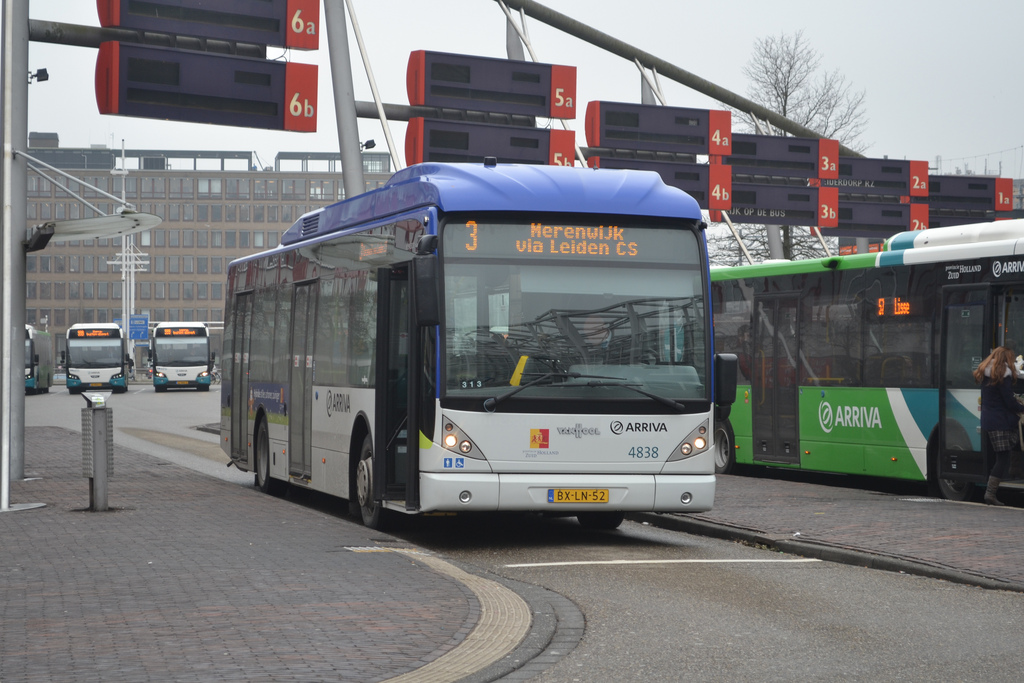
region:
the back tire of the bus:
[243, 407, 279, 488]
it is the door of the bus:
[366, 269, 439, 491]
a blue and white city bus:
[205, 149, 728, 535]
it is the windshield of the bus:
[439, 258, 703, 398]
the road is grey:
[176, 404, 982, 680]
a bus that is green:
[694, 243, 1023, 507]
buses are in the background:
[54, 315, 220, 411]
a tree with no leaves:
[742, 28, 841, 248]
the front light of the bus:
[661, 423, 719, 472]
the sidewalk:
[160, 588, 279, 633]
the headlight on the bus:
[678, 430, 701, 444]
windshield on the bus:
[443, 244, 691, 412]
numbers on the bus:
[620, 433, 656, 462]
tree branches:
[764, 45, 832, 109]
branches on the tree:
[746, 36, 819, 112]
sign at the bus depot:
[90, 0, 318, 49]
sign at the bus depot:
[89, 40, 315, 132]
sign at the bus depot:
[402, 46, 577, 119]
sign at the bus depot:
[402, 115, 574, 167]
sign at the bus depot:
[577, 93, 733, 157]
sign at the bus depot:
[577, 144, 734, 217]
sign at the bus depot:
[718, 122, 839, 179]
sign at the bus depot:
[721, 172, 839, 230]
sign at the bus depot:
[827, 194, 927, 232]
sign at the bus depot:
[839, 152, 932, 201]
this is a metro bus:
[96, 60, 1020, 636]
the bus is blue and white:
[222, 130, 719, 603]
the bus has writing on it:
[406, 221, 622, 297]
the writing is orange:
[400, 133, 780, 428]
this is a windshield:
[415, 282, 701, 466]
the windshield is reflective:
[424, 280, 710, 443]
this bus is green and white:
[725, 230, 997, 513]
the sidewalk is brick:
[102, 514, 333, 677]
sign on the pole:
[86, 9, 312, 44]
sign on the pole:
[114, 51, 314, 151]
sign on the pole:
[387, 37, 591, 127]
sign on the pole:
[396, 105, 586, 172]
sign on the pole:
[582, 98, 737, 162]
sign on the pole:
[590, 152, 718, 211]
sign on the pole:
[716, 138, 822, 174]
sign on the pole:
[699, 162, 827, 219]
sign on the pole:
[814, 196, 910, 238]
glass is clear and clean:
[444, 216, 707, 404]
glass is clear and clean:
[806, 296, 858, 382]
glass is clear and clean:
[865, 319, 938, 384]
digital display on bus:
[425, 203, 714, 277]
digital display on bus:
[434, 202, 719, 275]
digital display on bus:
[433, 208, 709, 275]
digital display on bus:
[424, 202, 718, 278]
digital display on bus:
[435, 193, 718, 274]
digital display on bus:
[427, 193, 719, 289]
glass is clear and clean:
[450, 258, 707, 402]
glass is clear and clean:
[323, 279, 352, 384]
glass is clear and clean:
[756, 306, 777, 452]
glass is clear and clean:
[802, 293, 867, 383]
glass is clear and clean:
[944, 284, 992, 383]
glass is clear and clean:
[716, 289, 751, 363]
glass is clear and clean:
[997, 296, 1021, 367]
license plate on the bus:
[546, 474, 622, 509]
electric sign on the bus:
[432, 211, 699, 269]